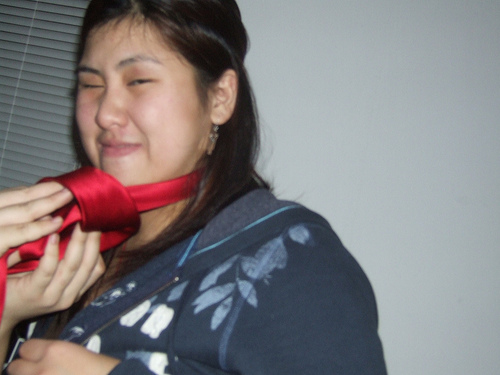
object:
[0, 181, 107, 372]
person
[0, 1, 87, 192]
blind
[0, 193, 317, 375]
jacket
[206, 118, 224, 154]
ear ring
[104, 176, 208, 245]
neck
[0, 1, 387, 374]
asian woman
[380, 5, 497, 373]
wall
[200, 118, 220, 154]
elephant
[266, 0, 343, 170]
wall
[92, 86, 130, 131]
nose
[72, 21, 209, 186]
face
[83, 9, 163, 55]
bangs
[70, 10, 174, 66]
forehead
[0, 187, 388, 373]
blue jacket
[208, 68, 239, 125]
ear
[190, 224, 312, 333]
print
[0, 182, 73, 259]
hand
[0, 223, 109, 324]
hand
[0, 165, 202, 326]
necktie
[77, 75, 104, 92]
eye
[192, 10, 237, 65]
hair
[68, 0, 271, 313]
hair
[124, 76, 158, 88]
eyes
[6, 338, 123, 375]
hand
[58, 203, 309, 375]
illustration